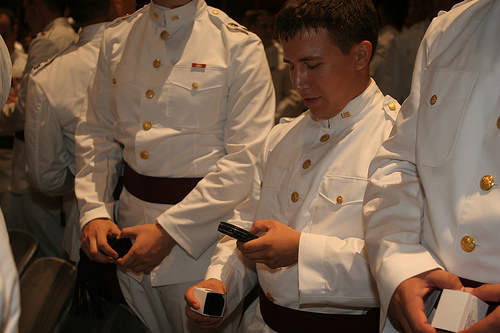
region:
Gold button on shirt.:
[453, 234, 498, 299]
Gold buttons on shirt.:
[282, 117, 329, 189]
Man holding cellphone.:
[234, 179, 271, 241]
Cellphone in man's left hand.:
[222, 157, 291, 296]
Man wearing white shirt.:
[282, 194, 374, 305]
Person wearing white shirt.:
[121, 105, 210, 286]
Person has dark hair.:
[331, 41, 376, 71]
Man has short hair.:
[273, 30, 371, 86]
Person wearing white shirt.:
[443, 180, 492, 264]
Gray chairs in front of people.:
[30, 259, 77, 322]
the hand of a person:
[123, 32, 273, 283]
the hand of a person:
[78, 67, 123, 269]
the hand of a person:
[226, 212, 388, 309]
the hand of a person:
[181, 199, 263, 325]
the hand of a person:
[370, 130, 463, 330]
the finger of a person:
[113, 240, 139, 265]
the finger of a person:
[236, 236, 261, 251]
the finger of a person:
[425, 260, 464, 301]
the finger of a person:
[403, 285, 429, 331]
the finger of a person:
[95, 230, 120, 260]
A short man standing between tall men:
[260, 18, 394, 310]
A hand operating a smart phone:
[212, 206, 313, 261]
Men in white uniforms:
[107, 1, 495, 313]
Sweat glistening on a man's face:
[285, 19, 341, 90]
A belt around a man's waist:
[113, 147, 236, 214]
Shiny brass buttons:
[459, 174, 495, 256]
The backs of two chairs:
[6, 226, 78, 322]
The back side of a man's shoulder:
[28, 30, 98, 114]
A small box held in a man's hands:
[425, 277, 483, 329]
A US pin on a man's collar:
[332, 105, 362, 126]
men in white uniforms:
[93, 6, 495, 317]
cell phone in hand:
[214, 214, 273, 259]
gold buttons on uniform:
[281, 149, 318, 208]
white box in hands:
[420, 271, 496, 331]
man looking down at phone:
[272, 19, 339, 126]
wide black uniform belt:
[116, 156, 203, 209]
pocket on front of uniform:
[165, 66, 227, 140]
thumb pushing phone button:
[236, 213, 278, 245]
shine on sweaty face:
[297, 22, 327, 60]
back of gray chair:
[11, 255, 94, 329]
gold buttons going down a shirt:
[140, 10, 190, 190]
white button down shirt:
[106, 9, 309, 258]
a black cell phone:
[196, 210, 288, 251]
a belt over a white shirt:
[92, 145, 279, 233]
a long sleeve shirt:
[91, 2, 280, 248]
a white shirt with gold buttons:
[73, 2, 292, 259]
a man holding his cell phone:
[167, 12, 427, 332]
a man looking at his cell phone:
[185, 16, 418, 315]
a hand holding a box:
[164, 258, 246, 331]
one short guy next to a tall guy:
[95, 6, 403, 322]